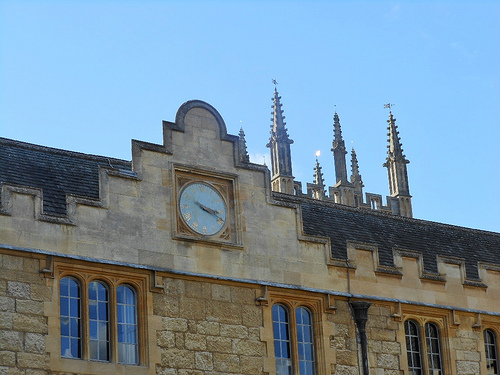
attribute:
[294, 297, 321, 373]
window — brown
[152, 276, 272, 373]
stones — tan 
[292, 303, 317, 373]
window — narrow, arched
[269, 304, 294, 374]
window — narrow, arched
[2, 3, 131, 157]
sky — blue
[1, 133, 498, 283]
roof — black 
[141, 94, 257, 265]
clock building — big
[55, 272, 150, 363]
window — narrow, arched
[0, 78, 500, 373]
building — big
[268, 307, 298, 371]
window — narrow, arched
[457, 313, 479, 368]
stone — big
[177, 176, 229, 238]
clock — round, big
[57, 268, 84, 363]
window — big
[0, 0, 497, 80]
blue sky — clear, big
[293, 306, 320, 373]
narrow window — big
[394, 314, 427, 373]
window — narrow, arch